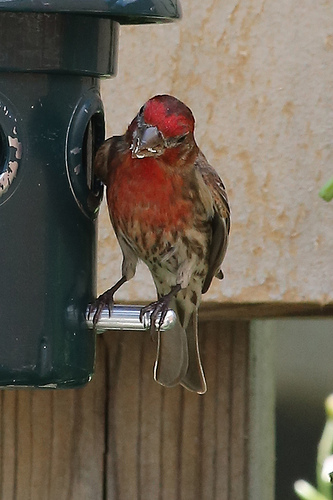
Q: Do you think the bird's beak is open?
A: Yes, the beak is open.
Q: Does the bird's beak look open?
A: Yes, the beak is open.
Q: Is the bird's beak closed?
A: No, the beak is open.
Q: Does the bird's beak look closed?
A: No, the beak is open.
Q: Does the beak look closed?
A: No, the beak is open.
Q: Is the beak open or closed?
A: The beak is open.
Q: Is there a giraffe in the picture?
A: No, there are no giraffes.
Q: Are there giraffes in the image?
A: No, there are no giraffes.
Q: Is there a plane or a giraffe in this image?
A: No, there are no giraffes or airplanes.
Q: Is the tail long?
A: Yes, the tail is long.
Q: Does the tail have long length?
A: Yes, the tail is long.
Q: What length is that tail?
A: The tail is long.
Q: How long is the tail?
A: The tail is long.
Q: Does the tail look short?
A: No, the tail is long.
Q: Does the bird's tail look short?
A: No, the tail is long.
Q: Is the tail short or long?
A: The tail is long.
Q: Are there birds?
A: Yes, there is a bird.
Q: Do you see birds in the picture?
A: Yes, there is a bird.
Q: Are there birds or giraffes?
A: Yes, there is a bird.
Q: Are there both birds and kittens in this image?
A: No, there is a bird but no kittens.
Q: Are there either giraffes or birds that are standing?
A: Yes, the bird is standing.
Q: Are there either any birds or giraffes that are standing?
A: Yes, the bird is standing.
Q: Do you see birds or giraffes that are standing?
A: Yes, the bird is standing.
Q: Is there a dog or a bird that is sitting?
A: Yes, the bird is sitting.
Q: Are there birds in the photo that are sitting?
A: Yes, there is a bird that is sitting.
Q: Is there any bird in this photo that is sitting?
A: Yes, there is a bird that is sitting.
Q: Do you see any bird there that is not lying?
A: Yes, there is a bird that is sitting .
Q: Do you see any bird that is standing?
A: Yes, there is a bird that is standing.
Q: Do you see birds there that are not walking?
A: Yes, there is a bird that is standing .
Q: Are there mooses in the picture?
A: No, there are no mooses.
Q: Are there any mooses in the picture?
A: No, there are no mooses.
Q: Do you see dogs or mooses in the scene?
A: No, there are no mooses or dogs.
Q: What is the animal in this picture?
A: The animal is a bird.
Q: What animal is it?
A: The animal is a bird.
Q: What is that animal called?
A: This is a bird.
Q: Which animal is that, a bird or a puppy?
A: This is a bird.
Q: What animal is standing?
A: The animal is a bird.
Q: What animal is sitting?
A: The animal is a bird.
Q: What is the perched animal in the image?
A: The animal is a bird.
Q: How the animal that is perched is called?
A: The animal is a bird.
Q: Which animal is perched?
A: The animal is a bird.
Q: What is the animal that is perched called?
A: The animal is a bird.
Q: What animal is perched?
A: The animal is a bird.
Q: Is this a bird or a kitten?
A: This is a bird.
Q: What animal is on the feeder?
A: The bird is on the feeder.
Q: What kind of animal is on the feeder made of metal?
A: The animal is a bird.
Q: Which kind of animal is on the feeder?
A: The animal is a bird.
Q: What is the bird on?
A: The bird is on the feeder.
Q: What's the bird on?
A: The bird is on the feeder.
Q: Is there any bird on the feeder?
A: Yes, there is a bird on the feeder.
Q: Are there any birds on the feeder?
A: Yes, there is a bird on the feeder.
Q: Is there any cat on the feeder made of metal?
A: No, there is a bird on the feeder.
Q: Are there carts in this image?
A: No, there are no carts.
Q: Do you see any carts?
A: No, there are no carts.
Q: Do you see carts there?
A: No, there are no carts.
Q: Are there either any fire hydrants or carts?
A: No, there are no carts or fire hydrants.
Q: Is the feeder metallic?
A: Yes, the feeder is metallic.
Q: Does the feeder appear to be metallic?
A: Yes, the feeder is metallic.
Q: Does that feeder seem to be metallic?
A: Yes, the feeder is metallic.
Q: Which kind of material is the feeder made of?
A: The feeder is made of metal.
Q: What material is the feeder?
A: The feeder is made of metal.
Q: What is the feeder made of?
A: The feeder is made of metal.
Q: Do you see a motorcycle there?
A: No, there are no motorcycles.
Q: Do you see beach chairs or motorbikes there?
A: No, there are no motorbikes or beach chairs.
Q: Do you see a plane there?
A: No, there are no airplanes.